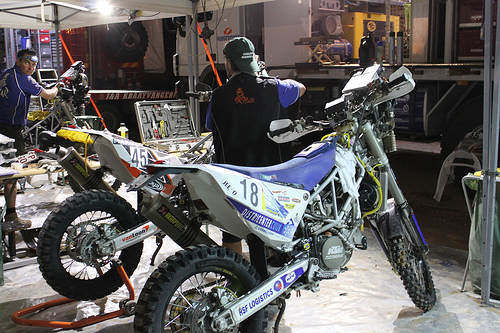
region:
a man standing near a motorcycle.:
[212, 23, 306, 173]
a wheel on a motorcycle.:
[126, 214, 283, 331]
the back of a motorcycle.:
[24, 91, 130, 184]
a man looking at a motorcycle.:
[0, 49, 85, 139]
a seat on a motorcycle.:
[199, 134, 343, 194]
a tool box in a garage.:
[107, 76, 228, 203]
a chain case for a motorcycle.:
[201, 219, 353, 319]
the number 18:
[223, 161, 274, 218]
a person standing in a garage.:
[424, 69, 478, 241]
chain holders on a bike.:
[67, 203, 152, 293]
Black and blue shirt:
[201, 69, 316, 182]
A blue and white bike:
[117, 131, 447, 331]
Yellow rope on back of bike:
[53, 126, 93, 156]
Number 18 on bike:
[231, 173, 270, 213]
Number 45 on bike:
[127, 142, 157, 179]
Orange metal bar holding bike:
[1, 261, 150, 331]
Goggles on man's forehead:
[6, 46, 42, 83]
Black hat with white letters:
[214, 23, 279, 96]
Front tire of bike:
[387, 196, 469, 317]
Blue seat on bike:
[211, 144, 355, 184]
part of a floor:
[343, 289, 359, 310]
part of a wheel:
[396, 270, 419, 295]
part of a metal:
[388, 182, 413, 212]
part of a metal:
[479, 247, 486, 280]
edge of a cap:
[242, 60, 257, 77]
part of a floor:
[345, 282, 377, 317]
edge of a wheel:
[198, 253, 233, 276]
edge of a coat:
[202, 95, 218, 137]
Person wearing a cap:
[218, 30, 263, 73]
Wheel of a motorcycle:
[377, 215, 442, 313]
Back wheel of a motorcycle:
[31, 185, 143, 300]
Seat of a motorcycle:
[212, 138, 355, 190]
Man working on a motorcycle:
[5, 42, 91, 140]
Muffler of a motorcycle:
[135, 185, 200, 241]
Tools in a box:
[132, 92, 198, 142]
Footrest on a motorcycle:
[303, 263, 339, 288]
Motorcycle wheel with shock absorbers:
[372, 207, 444, 315]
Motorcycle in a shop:
[131, 61, 442, 332]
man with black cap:
[206, 20, 307, 127]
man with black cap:
[205, 32, 341, 204]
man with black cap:
[191, 6, 276, 223]